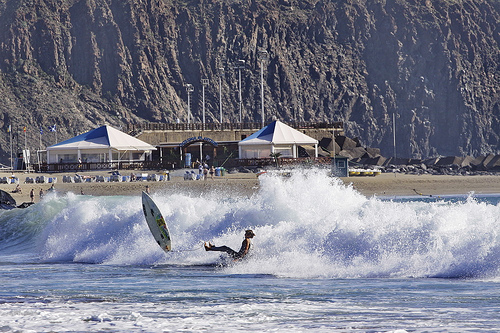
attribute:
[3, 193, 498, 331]
water — rambunctious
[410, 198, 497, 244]
ocean waves — white, blue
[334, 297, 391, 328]
ocean waves — white, blue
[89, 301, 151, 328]
ocean waves — white, blue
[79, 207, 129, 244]
ocean waves — white, blue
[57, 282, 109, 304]
ocean waves — white, blue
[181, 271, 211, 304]
waves — white, blue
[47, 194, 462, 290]
ocean waves — blue, white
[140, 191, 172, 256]
surfboard — white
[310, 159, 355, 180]
shed — small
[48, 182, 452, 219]
water — boisterous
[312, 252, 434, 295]
waves — white, blue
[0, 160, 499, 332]
water — powerful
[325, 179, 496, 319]
waves — ocean, white, blue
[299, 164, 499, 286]
waves — ocean, white, blue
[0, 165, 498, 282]
waves — white, blue, ocean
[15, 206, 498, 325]
water — choppy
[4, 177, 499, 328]
water — wavy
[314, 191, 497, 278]
ocean waves — blue, white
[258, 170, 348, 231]
ocean waves — blue, white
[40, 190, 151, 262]
ocean waves — blue, white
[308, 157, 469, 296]
waves — white, blue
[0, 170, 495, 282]
wave — large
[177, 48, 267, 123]
light posts — tall, white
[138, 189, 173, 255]
surfboard — airborne